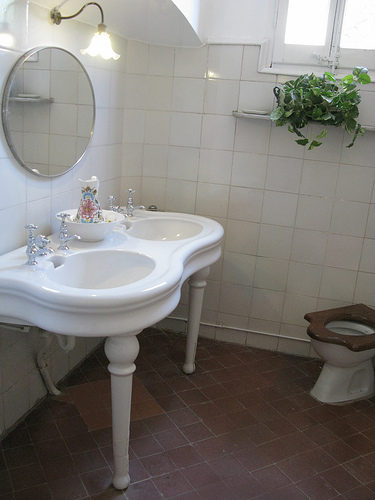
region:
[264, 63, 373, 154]
Green plant on shelf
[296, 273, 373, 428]
Toilet with wooden seat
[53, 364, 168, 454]
Lighter colored floor tiles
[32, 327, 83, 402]
Exposed plumbing for sink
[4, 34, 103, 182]
Round mirror above sink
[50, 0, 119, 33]
Chrome neck for light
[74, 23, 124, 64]
Fluted glass light shade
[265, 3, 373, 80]
Double bathroom window during the day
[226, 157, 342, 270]
White bathroom wall tiles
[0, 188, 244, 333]
Bathroom sink with two basins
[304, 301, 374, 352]
a wooden toilet seat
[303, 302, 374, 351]
the toilet seat is brown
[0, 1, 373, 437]
the wall is made of tile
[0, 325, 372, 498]
the floor is made of brick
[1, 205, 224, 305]
the sink is white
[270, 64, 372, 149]
a plant on the windowsill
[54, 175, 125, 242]
a floral pitcher on the sink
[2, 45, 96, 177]
a mirror over the sink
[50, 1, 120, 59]
a light over the sink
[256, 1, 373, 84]
a window over the plant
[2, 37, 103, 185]
round mirror with metal frame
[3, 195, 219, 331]
white porcelain double sink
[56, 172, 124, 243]
flowered basin and pitcher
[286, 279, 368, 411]
toilet with brown wood seat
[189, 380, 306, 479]
red floor tiles set in diamond pattern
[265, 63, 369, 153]
green houseplant on shelf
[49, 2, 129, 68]
wall mount light fixture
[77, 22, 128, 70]
glass light shade with scallop edging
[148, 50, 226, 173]
square white wall tiles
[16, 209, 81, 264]
chrome double faucet fixtures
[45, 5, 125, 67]
gold and glass light fixture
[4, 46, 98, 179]
round mirror with a silver frame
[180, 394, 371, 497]
dark brown tile floor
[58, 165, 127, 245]
white floral pitcher and basin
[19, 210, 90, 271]
silver sink fixtures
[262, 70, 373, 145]
small plant with green leaves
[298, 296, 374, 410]
white toilet with wooden seat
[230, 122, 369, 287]
white ceramic tile wall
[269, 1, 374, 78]
small glass window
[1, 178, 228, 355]
white double basin sink with silver fixtures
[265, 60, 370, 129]
green leaves below window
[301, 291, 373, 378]
brown wooden seat on toilet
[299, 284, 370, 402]
brown and white toilet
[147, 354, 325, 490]
brown tile floor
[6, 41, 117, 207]
round silver mirror above sink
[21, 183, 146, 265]
four shiny silver faucets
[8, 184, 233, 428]
white porcelain sink with two basins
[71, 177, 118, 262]
white blue and pink floral vase in bowl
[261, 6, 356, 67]
window with two panes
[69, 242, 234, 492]
two white sink legs